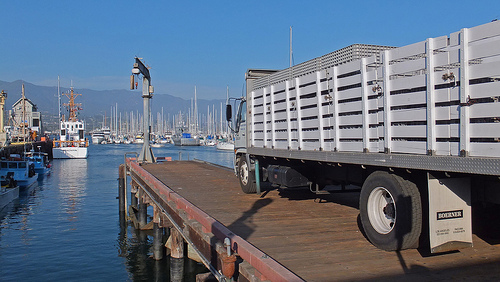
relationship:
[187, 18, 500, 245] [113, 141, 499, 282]
truck on pier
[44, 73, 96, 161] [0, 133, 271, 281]
boat in bay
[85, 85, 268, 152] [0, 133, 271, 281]
yachts in bay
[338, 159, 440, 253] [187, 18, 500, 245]
tire on truck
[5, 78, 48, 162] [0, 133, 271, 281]
building near bay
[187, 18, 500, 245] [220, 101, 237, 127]
truck has mirror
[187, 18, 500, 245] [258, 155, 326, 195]
truck has gas tank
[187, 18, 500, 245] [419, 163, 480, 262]
truck has mud flap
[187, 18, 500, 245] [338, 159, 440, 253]
truck has tire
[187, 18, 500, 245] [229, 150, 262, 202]
truck has tire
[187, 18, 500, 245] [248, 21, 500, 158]
truck has paneling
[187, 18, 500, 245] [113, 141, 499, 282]
truck parked on pier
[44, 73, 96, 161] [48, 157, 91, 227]
boat has reflection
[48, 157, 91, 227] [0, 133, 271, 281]
reflection in bay